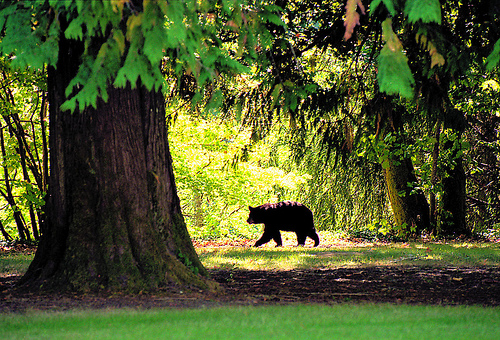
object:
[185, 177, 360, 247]
nature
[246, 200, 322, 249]
bear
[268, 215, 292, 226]
black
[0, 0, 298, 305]
tree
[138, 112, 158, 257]
giant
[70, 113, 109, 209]
bark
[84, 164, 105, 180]
moss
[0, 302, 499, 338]
grass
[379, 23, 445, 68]
leaves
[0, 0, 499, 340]
forest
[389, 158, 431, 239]
woods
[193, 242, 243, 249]
food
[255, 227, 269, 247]
guard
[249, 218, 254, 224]
teeth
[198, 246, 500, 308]
ground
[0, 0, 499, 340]
day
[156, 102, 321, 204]
sun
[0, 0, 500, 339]
park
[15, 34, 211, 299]
trunk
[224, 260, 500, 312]
shade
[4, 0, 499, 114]
foliage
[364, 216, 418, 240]
plant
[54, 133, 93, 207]
indentation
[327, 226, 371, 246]
leaves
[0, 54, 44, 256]
tree